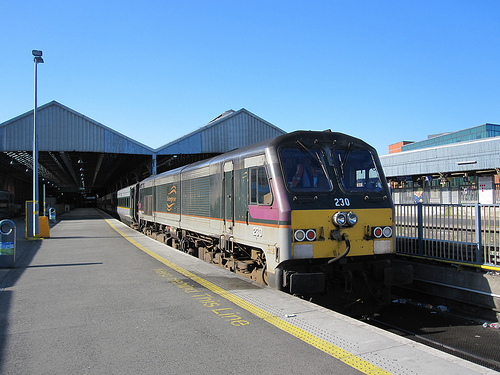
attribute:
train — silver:
[91, 125, 402, 303]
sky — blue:
[165, 17, 401, 83]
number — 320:
[331, 195, 352, 207]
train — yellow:
[112, 130, 396, 292]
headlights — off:
[289, 225, 323, 245]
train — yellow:
[103, 127, 413, 290]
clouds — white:
[109, 69, 204, 123]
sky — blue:
[76, 17, 486, 134]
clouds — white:
[66, 39, 141, 87]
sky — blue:
[66, 17, 440, 124]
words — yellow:
[161, 280, 308, 351]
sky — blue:
[153, 15, 368, 72]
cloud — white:
[121, 112, 170, 132]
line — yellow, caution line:
[96, 209, 383, 374]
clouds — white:
[61, 0, 309, 100]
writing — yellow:
[152, 267, 249, 328]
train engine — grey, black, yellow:
[132, 122, 404, 299]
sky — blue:
[2, 6, 497, 130]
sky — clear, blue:
[358, 51, 499, 75]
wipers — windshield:
[283, 138, 380, 193]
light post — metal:
[10, 25, 64, 246]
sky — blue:
[0, 1, 498, 156]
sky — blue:
[107, 13, 470, 90]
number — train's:
[329, 196, 353, 210]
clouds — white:
[17, 8, 407, 84]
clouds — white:
[108, 4, 446, 104]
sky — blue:
[1, 2, 469, 112]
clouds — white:
[42, 5, 479, 86]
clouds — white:
[39, 0, 469, 79]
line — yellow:
[108, 226, 301, 373]